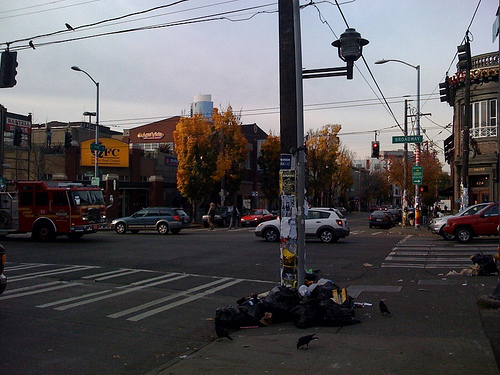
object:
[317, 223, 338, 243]
wheel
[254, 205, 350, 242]
car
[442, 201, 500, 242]
car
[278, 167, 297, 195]
ads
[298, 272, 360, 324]
man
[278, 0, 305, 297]
pole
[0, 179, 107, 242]
truck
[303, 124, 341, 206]
tree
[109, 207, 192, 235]
car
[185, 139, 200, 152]
leaves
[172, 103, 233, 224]
tree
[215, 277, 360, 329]
garbage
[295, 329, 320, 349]
bird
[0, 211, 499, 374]
road